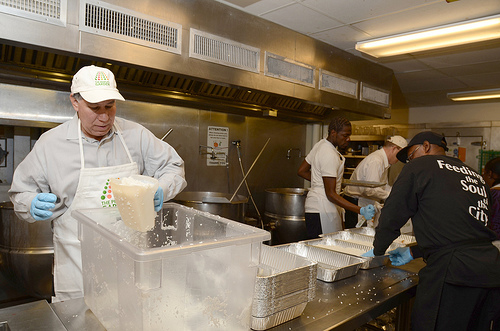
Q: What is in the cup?
A: Flour.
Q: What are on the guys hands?
A: Gloves.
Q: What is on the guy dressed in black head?
A: Hat.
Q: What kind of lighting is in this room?
A: Fluorescent.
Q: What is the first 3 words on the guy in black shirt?
A: Feeding the Soul.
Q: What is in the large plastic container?
A: Flour.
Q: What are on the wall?
A: Silver vents.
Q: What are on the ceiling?
A: Lights.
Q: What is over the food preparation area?
A: Vents.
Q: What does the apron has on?
A: Logo.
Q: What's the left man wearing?
A: Apron.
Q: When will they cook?
A: Now.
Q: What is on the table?
A: Trays.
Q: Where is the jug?
A: In the guys hand.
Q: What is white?
A: Apron.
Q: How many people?
A: 5.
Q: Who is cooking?
A: People.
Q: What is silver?
A: The trays.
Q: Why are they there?
A: To cook.